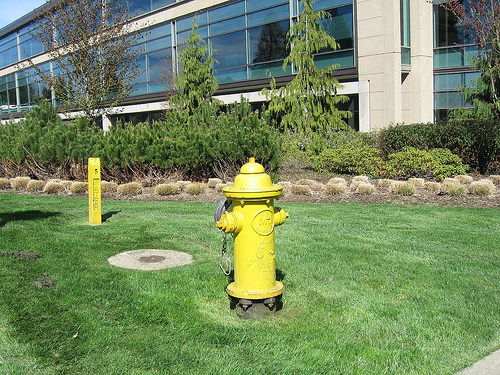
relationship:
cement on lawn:
[105, 246, 196, 274] [1, 185, 500, 374]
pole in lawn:
[84, 152, 108, 228] [1, 185, 500, 374]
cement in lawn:
[105, 246, 196, 274] [1, 185, 500, 374]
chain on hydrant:
[218, 230, 235, 276] [211, 153, 290, 317]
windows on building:
[172, 3, 355, 95] [2, 2, 495, 140]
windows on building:
[47, 19, 177, 108] [2, 2, 495, 140]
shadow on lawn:
[2, 206, 64, 239] [1, 185, 500, 374]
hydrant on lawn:
[211, 153, 290, 317] [1, 185, 500, 374]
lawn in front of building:
[1, 185, 500, 374] [2, 2, 495, 140]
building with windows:
[2, 2, 495, 140] [172, 3, 355, 95]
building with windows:
[2, 2, 495, 140] [47, 19, 177, 108]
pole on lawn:
[84, 152, 108, 228] [1, 185, 500, 374]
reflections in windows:
[245, 14, 289, 71] [172, 3, 355, 95]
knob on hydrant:
[237, 155, 267, 174] [211, 153, 290, 317]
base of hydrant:
[230, 298, 282, 323] [211, 153, 290, 317]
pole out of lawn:
[84, 152, 108, 228] [1, 185, 500, 374]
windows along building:
[47, 19, 177, 108] [2, 2, 495, 140]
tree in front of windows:
[8, 1, 159, 138] [47, 19, 177, 108]